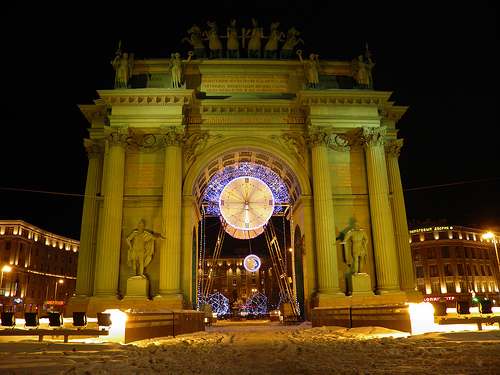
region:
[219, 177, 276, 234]
A clock with yellow hands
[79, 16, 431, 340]
Stone arch with figures and clock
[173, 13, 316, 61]
Dancing animals on top of arch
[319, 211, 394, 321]
Statue at the bottom of arch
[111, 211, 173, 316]
Statue on bottom left side of arch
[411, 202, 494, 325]
Building behind the arch on the right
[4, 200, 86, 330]
Building behind the arch on the left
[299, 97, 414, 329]
Columns on the right side of the arch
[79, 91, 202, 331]
Columns on the left side of the arch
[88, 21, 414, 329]
Arch with clock in the center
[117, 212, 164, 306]
Statue of man pointed right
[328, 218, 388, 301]
Statue of man pointing left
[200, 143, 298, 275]
Bright golden clock with purple lights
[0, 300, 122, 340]
Row of lights illuminating monument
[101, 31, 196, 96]
Two statues on left top of monument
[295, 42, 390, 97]
Two statues on right top of monument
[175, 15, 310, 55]
Six horses against a midnight sky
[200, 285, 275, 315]
Two trees decorated with purple lights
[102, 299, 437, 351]
Two short walls leading to monument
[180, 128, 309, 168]
Two angels at top of monument arch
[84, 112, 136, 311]
roman column on monument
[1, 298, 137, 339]
up-lighting for the monument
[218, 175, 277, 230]
clock in center of arch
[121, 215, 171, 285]
roman warrior statue on left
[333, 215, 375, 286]
roman warrior statue on right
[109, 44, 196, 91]
roman goddesses on top of monument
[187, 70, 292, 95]
writing at top center of monument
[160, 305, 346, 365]
sand walkway leading to monument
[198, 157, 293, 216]
purple lights adorn top of clock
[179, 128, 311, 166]
angles flank the arch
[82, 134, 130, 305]
a large stone pillar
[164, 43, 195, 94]
a statue on the arch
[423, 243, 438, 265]
a window on the building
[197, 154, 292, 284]
a large lit clock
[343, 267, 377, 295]
a stone pedestal under a statue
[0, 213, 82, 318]
a large building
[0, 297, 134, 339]
a row of lights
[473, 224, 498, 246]
a lit yellow light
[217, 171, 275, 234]
the round face of a clock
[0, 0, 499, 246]
a clear black sky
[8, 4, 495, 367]
Photo was taken at night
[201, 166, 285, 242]
A large clock is in view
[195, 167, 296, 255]
The clock is lit up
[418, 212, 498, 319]
Building is in the background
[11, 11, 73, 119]
The sky is dark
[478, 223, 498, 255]
Street lights are on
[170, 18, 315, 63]
Statues of horses are on the top of the building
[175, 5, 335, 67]
Six horse statues are on top of the building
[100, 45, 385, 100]
Statues of people are near the top of the building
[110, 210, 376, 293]
Statues of people are near the bottom of the building